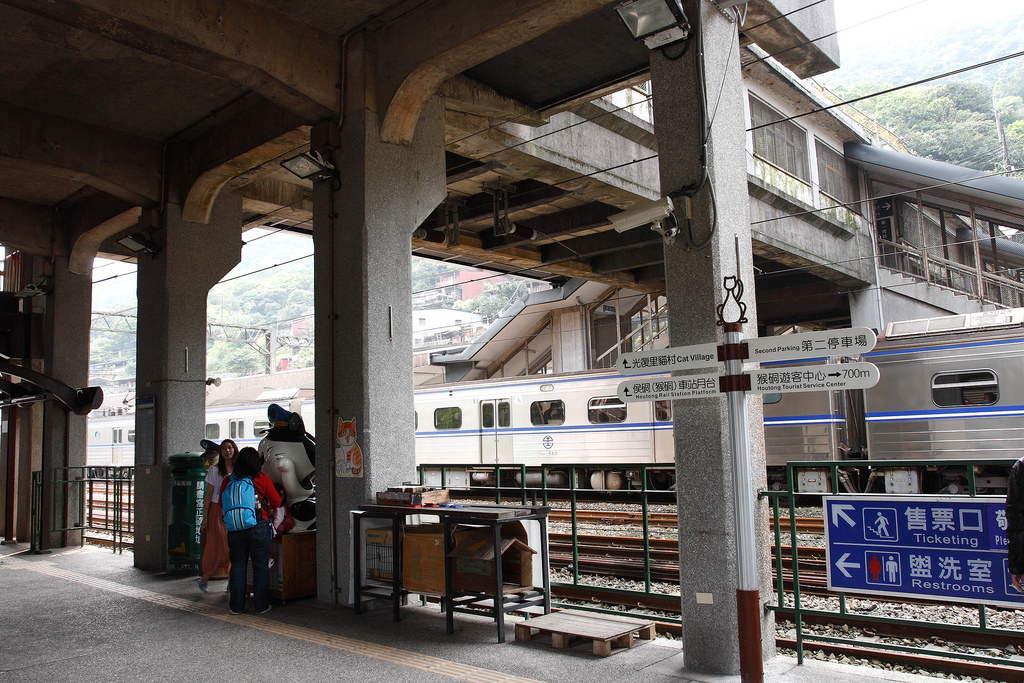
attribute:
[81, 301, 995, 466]
train — silver, white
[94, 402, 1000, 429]
stripe — blue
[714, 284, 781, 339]
metal sign — Metal 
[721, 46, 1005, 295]
covered walkway — Covered 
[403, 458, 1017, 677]
metal railing — Green 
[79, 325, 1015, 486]
silver train — silver 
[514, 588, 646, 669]
wooden palette — wooden 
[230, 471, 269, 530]
blue backpack — blue 